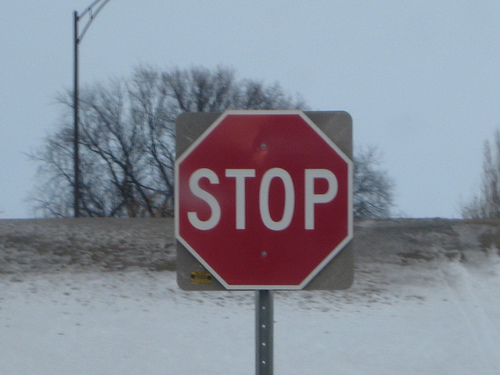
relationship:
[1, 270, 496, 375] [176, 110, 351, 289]
snow behind stop sign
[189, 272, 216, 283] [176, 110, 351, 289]
sticker on stop sign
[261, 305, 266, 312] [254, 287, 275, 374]
hole in pole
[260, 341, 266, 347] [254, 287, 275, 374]
hole in pole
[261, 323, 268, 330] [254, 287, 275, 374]
hole in pole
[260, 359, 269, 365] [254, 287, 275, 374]
hole in pole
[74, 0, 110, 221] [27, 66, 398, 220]
light pole next to trees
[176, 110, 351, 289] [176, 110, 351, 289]
stop sign behind stop sign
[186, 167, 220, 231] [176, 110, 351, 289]
letter on stop sign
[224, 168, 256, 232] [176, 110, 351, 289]
letter on stop sign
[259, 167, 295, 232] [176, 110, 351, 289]
letter on stop sign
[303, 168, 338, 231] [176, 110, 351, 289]
letter on stop sign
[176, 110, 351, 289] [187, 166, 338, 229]
stop sign has word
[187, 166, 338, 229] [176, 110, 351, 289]
word on stop sign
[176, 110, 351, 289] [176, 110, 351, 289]
stop sign against stop sign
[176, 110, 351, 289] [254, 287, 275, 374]
stop sign on pole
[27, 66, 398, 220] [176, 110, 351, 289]
trees behind stop sign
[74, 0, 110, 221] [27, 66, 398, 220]
light pole in front of trees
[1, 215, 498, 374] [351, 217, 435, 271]
ground has sandy area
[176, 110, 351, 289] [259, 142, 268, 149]
stop sign has screw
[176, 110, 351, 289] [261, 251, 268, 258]
stop sign has screw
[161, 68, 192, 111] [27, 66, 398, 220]
branches on trees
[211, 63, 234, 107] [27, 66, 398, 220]
branches on trees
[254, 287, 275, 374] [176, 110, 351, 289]
pole holding stop sign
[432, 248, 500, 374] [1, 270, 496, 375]
car tracks in snow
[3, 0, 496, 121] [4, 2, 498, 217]
clouds in sky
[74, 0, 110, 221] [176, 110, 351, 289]
light pole in back of stop sign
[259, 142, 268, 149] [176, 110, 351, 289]
top screw holding up stop sign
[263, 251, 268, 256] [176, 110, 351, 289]
bottom screw holding up stop sign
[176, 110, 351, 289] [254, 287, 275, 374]
stop sign mounted on pole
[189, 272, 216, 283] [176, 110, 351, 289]
sticker on back of stop sign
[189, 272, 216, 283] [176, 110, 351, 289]
sticker to left of stop sign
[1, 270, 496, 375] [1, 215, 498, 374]
snow covers ground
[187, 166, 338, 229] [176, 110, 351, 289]
word written in stop sign